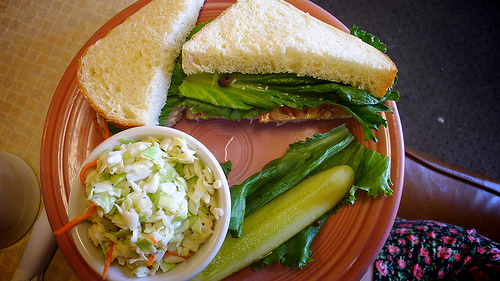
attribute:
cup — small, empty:
[2, 151, 59, 233]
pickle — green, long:
[256, 157, 374, 242]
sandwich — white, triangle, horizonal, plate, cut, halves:
[59, 4, 201, 132]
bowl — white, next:
[43, 107, 267, 280]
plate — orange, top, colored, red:
[11, 98, 107, 169]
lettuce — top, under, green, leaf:
[294, 118, 370, 171]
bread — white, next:
[227, 37, 335, 70]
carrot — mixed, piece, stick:
[58, 159, 114, 228]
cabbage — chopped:
[113, 172, 180, 230]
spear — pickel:
[205, 166, 357, 279]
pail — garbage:
[251, 100, 328, 130]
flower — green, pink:
[420, 237, 437, 258]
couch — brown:
[436, 171, 475, 207]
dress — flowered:
[401, 223, 468, 255]